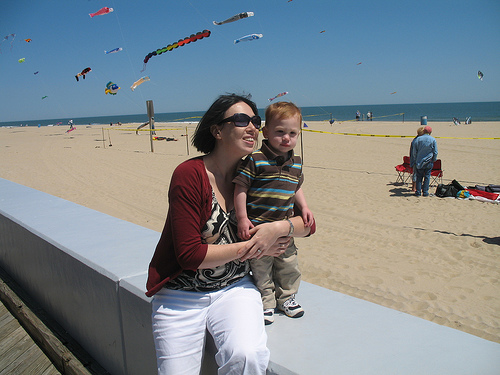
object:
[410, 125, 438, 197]
people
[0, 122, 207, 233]
sand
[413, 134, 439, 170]
shirt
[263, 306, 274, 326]
shoe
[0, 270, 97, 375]
boardwalk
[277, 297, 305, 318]
shoes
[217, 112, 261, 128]
sunglasses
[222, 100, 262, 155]
face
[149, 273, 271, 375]
pants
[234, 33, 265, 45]
kite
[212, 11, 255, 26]
kite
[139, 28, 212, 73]
kite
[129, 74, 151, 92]
kite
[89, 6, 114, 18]
kite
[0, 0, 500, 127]
sky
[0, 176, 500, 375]
wall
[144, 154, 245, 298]
brown sweater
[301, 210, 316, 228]
hand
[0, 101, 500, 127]
water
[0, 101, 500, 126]
ocean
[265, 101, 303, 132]
hair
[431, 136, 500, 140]
tape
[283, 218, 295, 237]
object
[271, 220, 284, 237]
wrist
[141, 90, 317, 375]
lady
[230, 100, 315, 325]
child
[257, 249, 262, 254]
ring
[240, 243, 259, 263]
finger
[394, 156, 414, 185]
chair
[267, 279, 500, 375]
concrete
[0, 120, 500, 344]
beach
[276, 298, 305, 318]
feet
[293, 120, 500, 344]
sand